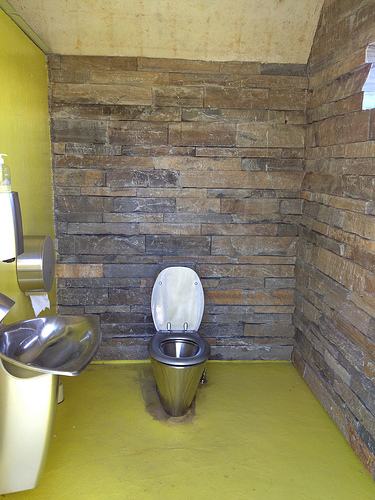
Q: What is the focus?
A: Toilet.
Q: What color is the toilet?
A: Chrome.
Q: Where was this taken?
A: Bathroom.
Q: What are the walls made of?
A: Stone.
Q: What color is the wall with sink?
A: Green.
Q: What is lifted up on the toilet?
A: Seat.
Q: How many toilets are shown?
A: 1.